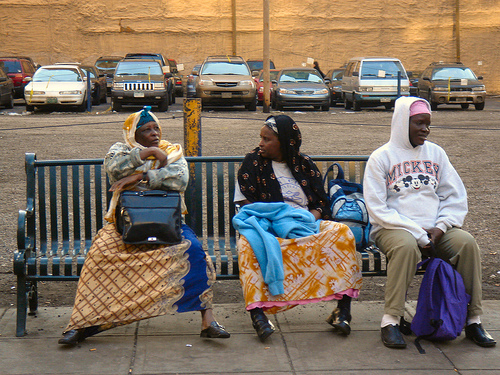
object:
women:
[57, 106, 234, 344]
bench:
[11, 147, 449, 337]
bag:
[113, 186, 184, 244]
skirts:
[59, 217, 216, 333]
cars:
[24, 63, 89, 111]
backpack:
[407, 239, 465, 353]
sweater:
[229, 197, 324, 299]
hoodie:
[363, 94, 470, 246]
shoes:
[464, 320, 496, 344]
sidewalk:
[0, 299, 499, 375]